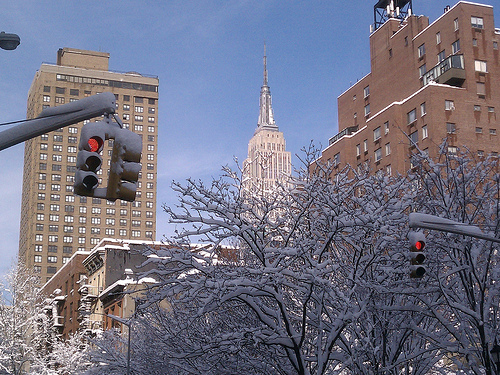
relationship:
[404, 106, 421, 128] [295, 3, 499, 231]
window on building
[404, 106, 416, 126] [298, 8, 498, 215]
window on bulding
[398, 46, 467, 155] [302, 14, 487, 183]
glass window on building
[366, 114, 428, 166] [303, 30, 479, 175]
window on building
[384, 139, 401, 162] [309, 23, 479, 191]
window on building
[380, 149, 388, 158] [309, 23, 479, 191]
glass window on building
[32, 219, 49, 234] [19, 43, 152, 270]
window on building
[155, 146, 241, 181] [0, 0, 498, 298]
cloud in blue sky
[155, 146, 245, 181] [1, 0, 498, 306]
cloud in sky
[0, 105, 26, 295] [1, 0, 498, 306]
cloud in sky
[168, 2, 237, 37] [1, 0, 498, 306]
cloud in sky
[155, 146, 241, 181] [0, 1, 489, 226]
cloud in sky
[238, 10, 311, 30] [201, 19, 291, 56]
white clouds in sky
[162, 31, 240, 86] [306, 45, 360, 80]
white clouds in sky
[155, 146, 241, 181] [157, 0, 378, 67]
cloud in blue sky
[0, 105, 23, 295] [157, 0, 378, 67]
cloud in blue sky